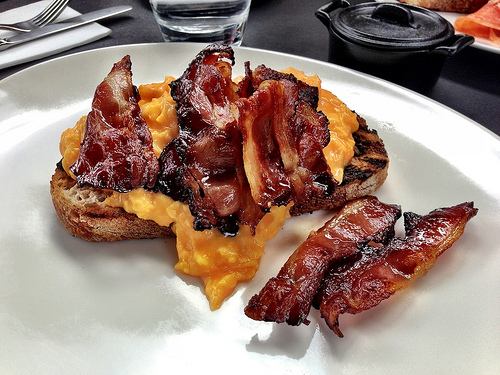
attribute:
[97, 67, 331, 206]
bacon — brown, red, burnt, crispy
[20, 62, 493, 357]
plate — white, ceramic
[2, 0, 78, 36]
fork — silver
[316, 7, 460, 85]
pot — black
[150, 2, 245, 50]
glass — clear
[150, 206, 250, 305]
cheese — orange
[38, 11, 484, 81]
table — black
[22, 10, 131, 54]
knife — silver